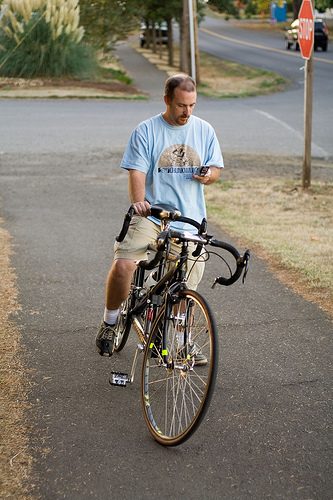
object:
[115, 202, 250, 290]
handle bar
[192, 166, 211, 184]
hand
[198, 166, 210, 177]
cellphone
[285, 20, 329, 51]
vehicle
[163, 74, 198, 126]
head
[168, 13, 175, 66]
truck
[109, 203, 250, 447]
bicycle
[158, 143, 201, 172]
logo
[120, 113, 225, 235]
shirt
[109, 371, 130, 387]
pedal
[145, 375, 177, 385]
spoke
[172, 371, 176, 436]
spoke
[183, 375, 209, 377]
spoke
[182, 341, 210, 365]
spoke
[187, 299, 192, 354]
spoke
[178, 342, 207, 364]
tennis shoe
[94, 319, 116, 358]
tennis shoe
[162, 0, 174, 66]
trees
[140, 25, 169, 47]
van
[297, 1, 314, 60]
sign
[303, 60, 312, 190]
wooden post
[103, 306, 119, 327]
socks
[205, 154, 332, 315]
brown grass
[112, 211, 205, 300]
shorts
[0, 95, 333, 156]
street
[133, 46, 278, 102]
grass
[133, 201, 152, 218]
hand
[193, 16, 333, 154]
road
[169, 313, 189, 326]
pedal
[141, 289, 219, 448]
wheel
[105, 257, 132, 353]
wheel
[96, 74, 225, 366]
guy